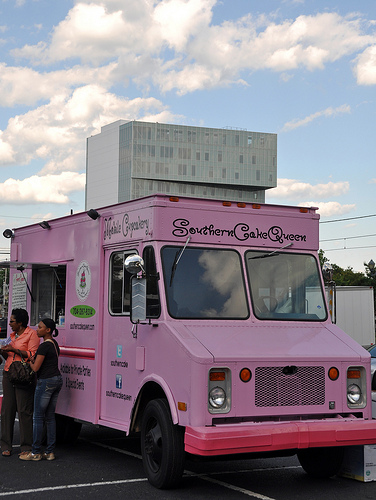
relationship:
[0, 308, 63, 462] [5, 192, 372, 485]
people are standing by truck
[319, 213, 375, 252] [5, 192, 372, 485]
electrical lines are behind truck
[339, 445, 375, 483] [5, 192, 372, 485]
box next to truck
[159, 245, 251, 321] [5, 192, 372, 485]
windshield of truck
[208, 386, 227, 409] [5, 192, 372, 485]
headlight of truck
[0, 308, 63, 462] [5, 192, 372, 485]
people beside truck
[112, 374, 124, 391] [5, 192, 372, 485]
facebook logo on truck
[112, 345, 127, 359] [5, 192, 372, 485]
twitter logo on truck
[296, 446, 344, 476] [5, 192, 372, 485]
tire of truck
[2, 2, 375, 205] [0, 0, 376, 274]
clouds in sky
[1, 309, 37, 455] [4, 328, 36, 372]
woman wears a shirt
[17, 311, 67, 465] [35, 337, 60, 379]
people wears a shirt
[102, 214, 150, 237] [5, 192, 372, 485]
writing on truck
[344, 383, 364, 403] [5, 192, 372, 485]
headlight on truck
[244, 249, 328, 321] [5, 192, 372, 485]
windshield of truck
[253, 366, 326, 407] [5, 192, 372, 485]
grille on truck